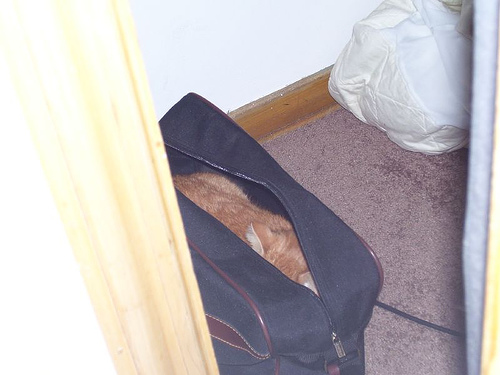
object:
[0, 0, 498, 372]
door frame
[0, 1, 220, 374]
trim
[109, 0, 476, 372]
door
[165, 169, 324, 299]
cat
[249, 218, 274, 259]
ears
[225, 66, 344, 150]
border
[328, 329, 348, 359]
zipper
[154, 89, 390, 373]
bag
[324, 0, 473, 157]
bag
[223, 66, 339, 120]
board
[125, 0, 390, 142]
wall